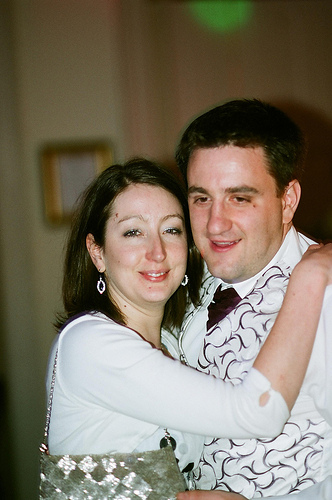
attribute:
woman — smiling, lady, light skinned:
[43, 156, 330, 500]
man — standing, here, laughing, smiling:
[175, 99, 330, 500]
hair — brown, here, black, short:
[176, 101, 301, 197]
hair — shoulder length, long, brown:
[52, 157, 200, 335]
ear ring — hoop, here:
[96, 274, 106, 293]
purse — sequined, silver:
[37, 314, 193, 499]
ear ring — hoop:
[177, 274, 189, 288]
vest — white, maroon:
[175, 226, 331, 497]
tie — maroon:
[208, 284, 239, 330]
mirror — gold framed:
[37, 135, 120, 228]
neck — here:
[101, 282, 168, 339]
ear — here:
[84, 235, 107, 276]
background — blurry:
[0, 2, 331, 94]